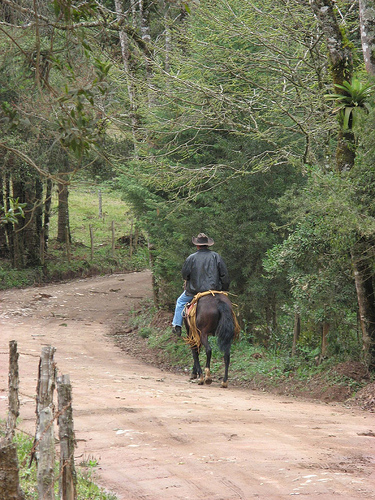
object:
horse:
[183, 293, 235, 387]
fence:
[0, 339, 75, 500]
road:
[73, 365, 375, 499]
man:
[172, 232, 230, 337]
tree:
[249, 0, 375, 376]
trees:
[0, 0, 186, 277]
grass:
[70, 206, 123, 233]